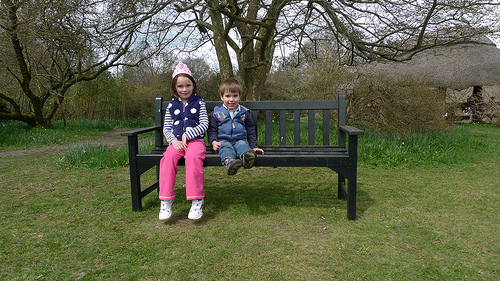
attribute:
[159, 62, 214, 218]
child — sitting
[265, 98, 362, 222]
bench — wooden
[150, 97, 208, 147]
shirt — striped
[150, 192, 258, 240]
shoes — white and pink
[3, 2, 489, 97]
tree — dry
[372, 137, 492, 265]
grass — green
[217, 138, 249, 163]
jeans — blue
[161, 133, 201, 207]
trousers — pink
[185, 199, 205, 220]
sneaker — white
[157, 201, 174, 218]
sneaker — white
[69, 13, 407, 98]
tree — leafless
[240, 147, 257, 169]
shoe — black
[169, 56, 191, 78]
tiara — lpink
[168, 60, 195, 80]
hat — pink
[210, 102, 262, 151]
shirt — blue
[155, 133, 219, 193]
pants — pink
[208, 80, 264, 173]
child — sitting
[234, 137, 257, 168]
leg — sticking out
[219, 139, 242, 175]
leg — sticking out